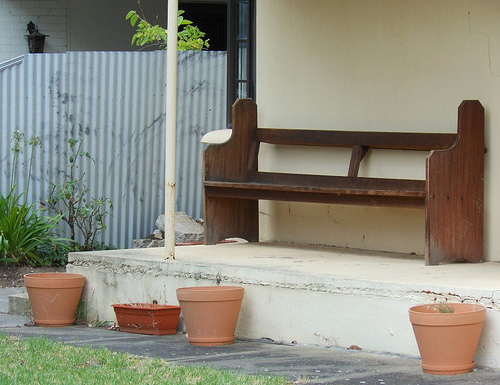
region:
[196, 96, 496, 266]
wooden bench with open back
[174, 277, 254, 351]
terra cotta pot with no plant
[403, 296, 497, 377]
terra cotta planter with small plant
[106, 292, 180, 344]
rectangular terra cotta pot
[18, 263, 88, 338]
terra cotta pot on the sidewalk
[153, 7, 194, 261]
white pole holding up porch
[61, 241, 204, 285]
edge of dirty white stoop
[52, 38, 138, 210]
tall white plastic fence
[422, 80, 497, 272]
wooden end of a bench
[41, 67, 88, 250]
skinny sapling in a garden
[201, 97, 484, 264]
Wooden bench on concrete pad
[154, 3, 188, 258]
White metal support pole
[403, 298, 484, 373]
Teracotta plant pot on sidewalk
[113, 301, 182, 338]
Rectangular plant pot on ground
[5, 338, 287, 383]
Patch of green grass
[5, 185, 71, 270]
Plant with long green leaves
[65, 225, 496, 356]
White cement pad against wall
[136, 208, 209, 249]
Large jagged rock on ground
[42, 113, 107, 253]
Young thin trees near metal wall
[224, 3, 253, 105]
Glass window on wall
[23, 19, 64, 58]
a black planter pot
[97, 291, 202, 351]
a rectangular terra cotta plant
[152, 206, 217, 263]
a stack of gray racks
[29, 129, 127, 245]
a tall skinny plant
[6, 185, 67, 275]
a bushy dark green plant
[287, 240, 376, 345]
white stone slab step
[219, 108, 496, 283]
a brown wooden church bench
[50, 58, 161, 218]
a gray metal fence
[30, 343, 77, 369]
a green grass small area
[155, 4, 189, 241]
a cream colored pole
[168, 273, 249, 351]
orange ceramic plant pot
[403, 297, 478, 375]
orange ceramic plant pot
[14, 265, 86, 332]
orange ceramic plant pot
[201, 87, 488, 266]
wooden bench against wall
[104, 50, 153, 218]
corrugated tin sheet wall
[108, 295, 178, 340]
orange square planter box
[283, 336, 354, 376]
concrete sidewalk by grass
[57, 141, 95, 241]
green tree growing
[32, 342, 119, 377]
patch of green grass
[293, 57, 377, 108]
beige wall by bench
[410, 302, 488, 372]
a light clay pot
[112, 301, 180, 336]
a dark clay pot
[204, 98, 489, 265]
a light stained wood bench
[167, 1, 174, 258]
a white metal pole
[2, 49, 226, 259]
a sheet metal fence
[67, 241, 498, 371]
a white concrete porch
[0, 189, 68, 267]
a short green plant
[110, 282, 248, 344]
a round pot and a rectangular pot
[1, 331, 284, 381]
grass by a walkway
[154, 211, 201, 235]
rock behind a pole